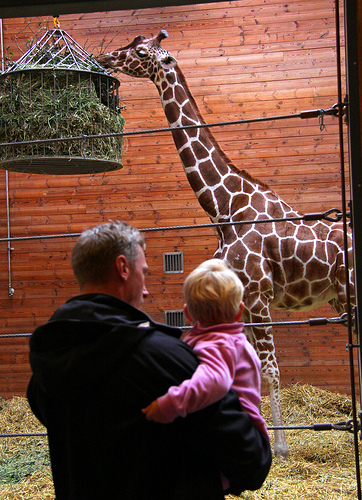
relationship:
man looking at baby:
[29, 222, 281, 498] [138, 255, 266, 437]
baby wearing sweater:
[138, 255, 266, 437] [156, 322, 267, 439]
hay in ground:
[226, 383, 357, 498] [224, 382, 361, 498]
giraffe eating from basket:
[95, 32, 360, 463] [1, 26, 126, 174]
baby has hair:
[138, 255, 266, 437] [186, 259, 244, 318]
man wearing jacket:
[29, 222, 281, 498] [25, 291, 271, 498]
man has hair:
[29, 222, 281, 498] [73, 220, 145, 291]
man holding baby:
[29, 222, 281, 498] [138, 255, 266, 437]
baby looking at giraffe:
[138, 255, 266, 437] [95, 32, 360, 463]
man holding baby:
[23, 217, 274, 498] [176, 261, 250, 350]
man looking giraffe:
[29, 222, 281, 498] [95, 32, 360, 463]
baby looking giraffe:
[138, 255, 265, 486] [95, 32, 360, 463]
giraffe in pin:
[95, 32, 360, 463] [1, 4, 361, 494]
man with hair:
[23, 217, 274, 498] [70, 216, 136, 283]